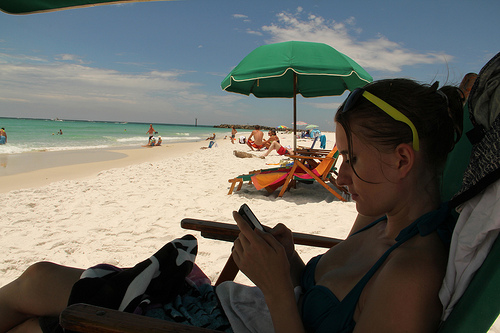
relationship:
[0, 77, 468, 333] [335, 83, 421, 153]
girl has sunglasses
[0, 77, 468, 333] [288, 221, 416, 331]
girl wearing a bikini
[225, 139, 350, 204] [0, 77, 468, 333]
chair near girl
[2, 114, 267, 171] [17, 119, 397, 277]
water at beach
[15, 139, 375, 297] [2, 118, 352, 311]
sand at beach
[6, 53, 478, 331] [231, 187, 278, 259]
girl on cellphone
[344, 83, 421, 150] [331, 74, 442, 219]
sunglasses on top of head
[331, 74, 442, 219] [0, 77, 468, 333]
head of girl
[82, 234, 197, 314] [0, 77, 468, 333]
towel in lap of girl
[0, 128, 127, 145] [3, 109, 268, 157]
people in water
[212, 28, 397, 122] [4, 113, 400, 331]
umbrella on beach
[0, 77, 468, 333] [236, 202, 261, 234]
girl texting on cellphone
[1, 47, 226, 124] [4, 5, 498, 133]
clouds in sky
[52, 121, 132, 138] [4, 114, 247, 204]
people in water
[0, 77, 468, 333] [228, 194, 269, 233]
girl looking at her cellphone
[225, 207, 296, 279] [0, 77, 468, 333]
hands of a girl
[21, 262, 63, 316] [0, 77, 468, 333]
knee of a girl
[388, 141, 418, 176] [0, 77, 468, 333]
ear of a girl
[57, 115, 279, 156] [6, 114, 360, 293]
people on beach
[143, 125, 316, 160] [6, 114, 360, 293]
people at beach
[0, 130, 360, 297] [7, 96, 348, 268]
sand of a beach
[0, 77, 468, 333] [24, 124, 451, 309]
girl sitting on beach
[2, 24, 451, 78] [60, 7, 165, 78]
clouds in sky